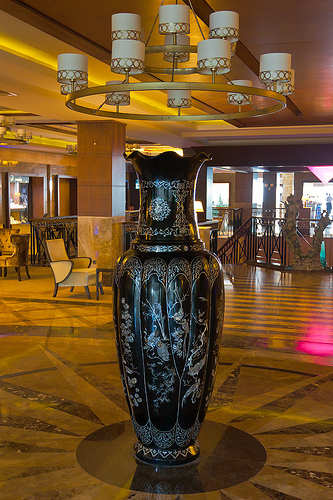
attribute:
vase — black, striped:
[111, 161, 247, 449]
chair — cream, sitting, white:
[38, 231, 103, 303]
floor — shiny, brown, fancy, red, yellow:
[234, 310, 313, 405]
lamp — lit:
[198, 195, 212, 220]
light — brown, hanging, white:
[113, 19, 240, 59]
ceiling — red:
[271, 10, 310, 44]